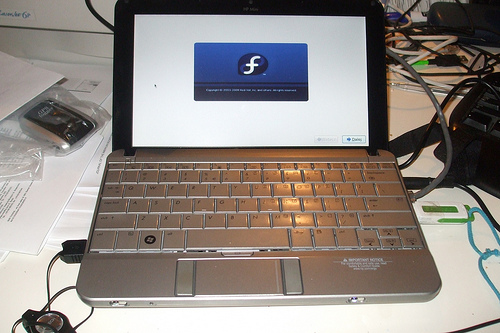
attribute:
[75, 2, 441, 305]
computer — windows'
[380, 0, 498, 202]
wires — a bunch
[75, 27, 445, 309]
laptop — open, powered on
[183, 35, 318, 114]
logo — facebook's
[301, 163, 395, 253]
keys — some, with orange glow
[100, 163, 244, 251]
keys — with orange glow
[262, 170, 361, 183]
keys — with orange glow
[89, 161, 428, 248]
keys — with orange glow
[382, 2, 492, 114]
wires — a blush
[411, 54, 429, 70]
marker — bright green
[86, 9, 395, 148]
screen — laptop's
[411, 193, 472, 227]
usb — plugged in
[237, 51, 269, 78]
'f' — white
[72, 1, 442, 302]
laptop — silver